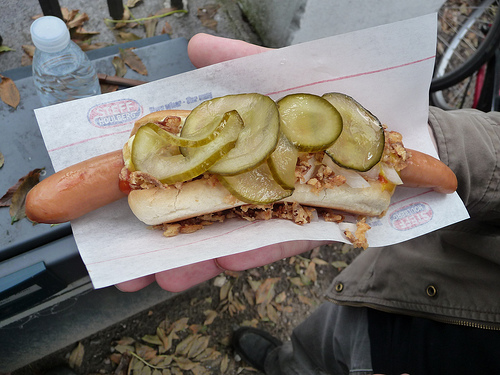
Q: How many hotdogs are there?
A: One.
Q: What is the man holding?
A: A hotdog.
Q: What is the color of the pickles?
A: Green.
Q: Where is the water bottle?
A: On the bench.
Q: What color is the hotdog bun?
A: Brown.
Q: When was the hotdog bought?
A: Earlier.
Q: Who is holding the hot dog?
A: A person.